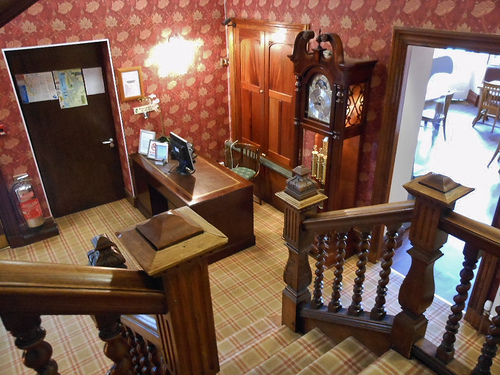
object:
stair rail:
[275, 169, 473, 373]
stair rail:
[1, 207, 232, 374]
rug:
[0, 193, 498, 372]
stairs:
[220, 319, 440, 374]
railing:
[313, 235, 327, 309]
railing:
[327, 230, 346, 313]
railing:
[345, 229, 370, 316]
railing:
[370, 226, 399, 321]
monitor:
[168, 131, 193, 177]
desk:
[126, 145, 257, 261]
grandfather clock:
[286, 31, 379, 267]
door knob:
[99, 137, 117, 151]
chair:
[225, 139, 267, 209]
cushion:
[227, 165, 257, 183]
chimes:
[308, 144, 326, 189]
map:
[52, 66, 91, 113]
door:
[2, 44, 124, 221]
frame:
[115, 65, 144, 104]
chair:
[476, 84, 499, 136]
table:
[485, 80, 497, 89]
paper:
[81, 67, 107, 95]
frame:
[152, 142, 168, 165]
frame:
[147, 139, 160, 160]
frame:
[137, 127, 155, 157]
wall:
[223, 0, 499, 238]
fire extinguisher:
[11, 179, 46, 229]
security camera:
[220, 14, 236, 32]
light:
[145, 36, 207, 77]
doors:
[225, 18, 307, 211]